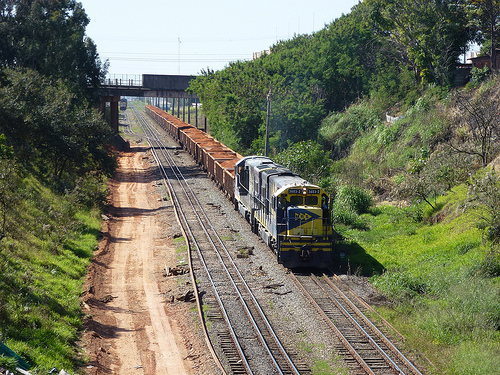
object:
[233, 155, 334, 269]
train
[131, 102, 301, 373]
track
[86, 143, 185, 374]
dirt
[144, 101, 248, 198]
train cars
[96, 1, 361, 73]
sky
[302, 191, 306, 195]
lights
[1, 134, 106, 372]
grass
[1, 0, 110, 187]
trees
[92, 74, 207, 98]
bridge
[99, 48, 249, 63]
electrical wires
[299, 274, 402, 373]
track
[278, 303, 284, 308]
rocks